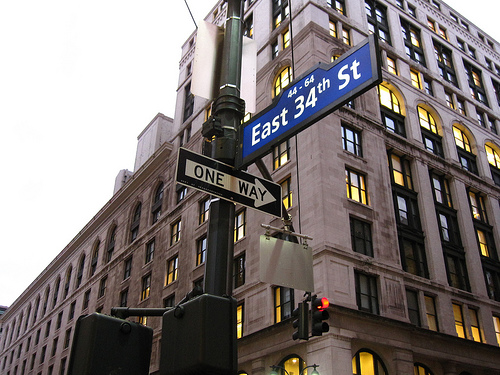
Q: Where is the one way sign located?
A: Underneath the blue sign.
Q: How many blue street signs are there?
A: 1.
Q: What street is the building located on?
A: East 34th St.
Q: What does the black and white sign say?
A: One way.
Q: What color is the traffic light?
A: Red.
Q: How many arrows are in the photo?
A: 1.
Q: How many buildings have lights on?
A: 1.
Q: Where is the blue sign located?
A: Above the black and white sign.